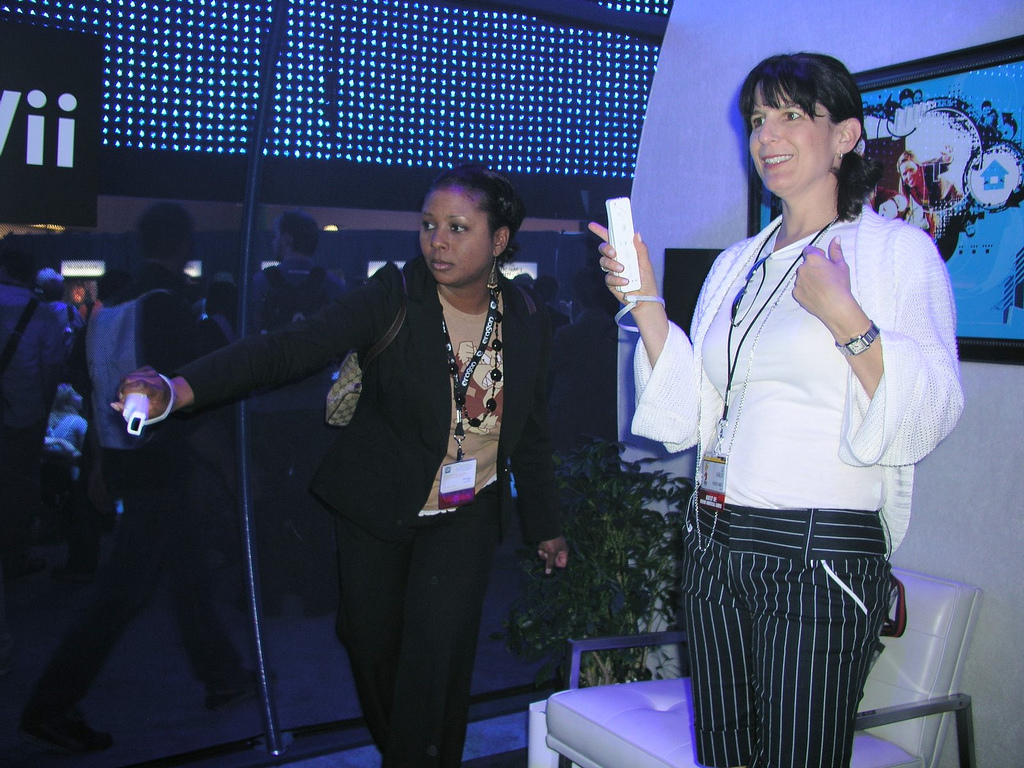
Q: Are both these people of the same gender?
A: Yes, all the people are female.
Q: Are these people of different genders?
A: No, all the people are female.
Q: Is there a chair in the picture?
A: Yes, there is a chair.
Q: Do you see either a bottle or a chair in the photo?
A: Yes, there is a chair.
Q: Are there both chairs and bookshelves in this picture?
A: No, there is a chair but no bookshelves.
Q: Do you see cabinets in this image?
A: No, there are no cabinets.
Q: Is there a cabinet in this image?
A: No, there are no cabinets.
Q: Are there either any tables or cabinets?
A: No, there are no cabinets or tables.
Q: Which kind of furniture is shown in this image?
A: The furniture is a chair.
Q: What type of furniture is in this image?
A: The furniture is a chair.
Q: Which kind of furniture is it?
A: The piece of furniture is a chair.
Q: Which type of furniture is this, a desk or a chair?
A: That is a chair.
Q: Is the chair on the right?
A: Yes, the chair is on the right of the image.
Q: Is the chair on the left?
A: No, the chair is on the right of the image.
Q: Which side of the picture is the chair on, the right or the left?
A: The chair is on the right of the image.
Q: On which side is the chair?
A: The chair is on the right of the image.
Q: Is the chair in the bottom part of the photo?
A: Yes, the chair is in the bottom of the image.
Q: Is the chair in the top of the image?
A: No, the chair is in the bottom of the image.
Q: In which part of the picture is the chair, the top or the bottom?
A: The chair is in the bottom of the image.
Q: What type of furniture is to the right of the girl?
A: The piece of furniture is a chair.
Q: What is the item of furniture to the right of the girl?
A: The piece of furniture is a chair.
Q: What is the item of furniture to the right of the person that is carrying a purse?
A: The piece of furniture is a chair.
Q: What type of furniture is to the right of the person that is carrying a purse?
A: The piece of furniture is a chair.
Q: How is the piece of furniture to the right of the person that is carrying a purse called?
A: The piece of furniture is a chair.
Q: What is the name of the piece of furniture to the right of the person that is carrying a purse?
A: The piece of furniture is a chair.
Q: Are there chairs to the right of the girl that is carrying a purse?
A: Yes, there is a chair to the right of the girl.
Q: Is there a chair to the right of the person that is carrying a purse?
A: Yes, there is a chair to the right of the girl.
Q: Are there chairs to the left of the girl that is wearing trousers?
A: No, the chair is to the right of the girl.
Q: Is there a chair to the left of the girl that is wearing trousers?
A: No, the chair is to the right of the girl.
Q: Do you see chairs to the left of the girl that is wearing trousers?
A: No, the chair is to the right of the girl.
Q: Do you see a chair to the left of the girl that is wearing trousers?
A: No, the chair is to the right of the girl.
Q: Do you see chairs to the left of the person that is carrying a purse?
A: No, the chair is to the right of the girl.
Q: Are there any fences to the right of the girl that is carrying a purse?
A: No, there is a chair to the right of the girl.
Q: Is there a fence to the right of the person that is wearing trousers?
A: No, there is a chair to the right of the girl.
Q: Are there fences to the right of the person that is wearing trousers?
A: No, there is a chair to the right of the girl.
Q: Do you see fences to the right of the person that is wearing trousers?
A: No, there is a chair to the right of the girl.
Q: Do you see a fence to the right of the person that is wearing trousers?
A: No, there is a chair to the right of the girl.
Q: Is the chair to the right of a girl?
A: Yes, the chair is to the right of a girl.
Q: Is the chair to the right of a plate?
A: No, the chair is to the right of a girl.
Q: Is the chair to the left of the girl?
A: No, the chair is to the right of the girl.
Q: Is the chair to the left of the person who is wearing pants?
A: No, the chair is to the right of the girl.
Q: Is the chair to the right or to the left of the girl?
A: The chair is to the right of the girl.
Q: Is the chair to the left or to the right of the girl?
A: The chair is to the right of the girl.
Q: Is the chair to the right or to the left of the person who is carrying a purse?
A: The chair is to the right of the girl.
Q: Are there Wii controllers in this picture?
A: Yes, there is a Wii controller.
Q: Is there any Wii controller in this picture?
A: Yes, there is a Wii controller.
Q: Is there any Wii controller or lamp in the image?
A: Yes, there is a Wii controller.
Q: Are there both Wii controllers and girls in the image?
A: Yes, there are both a Wii controller and a girl.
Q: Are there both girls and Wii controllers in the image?
A: Yes, there are both a Wii controller and a girl.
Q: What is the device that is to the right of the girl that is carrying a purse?
A: The device is a Wii controller.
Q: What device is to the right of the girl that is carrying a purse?
A: The device is a Wii controller.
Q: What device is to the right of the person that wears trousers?
A: The device is a Wii controller.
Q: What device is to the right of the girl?
A: The device is a Wii controller.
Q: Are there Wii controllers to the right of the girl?
A: Yes, there is a Wii controller to the right of the girl.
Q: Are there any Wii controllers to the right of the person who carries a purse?
A: Yes, there is a Wii controller to the right of the girl.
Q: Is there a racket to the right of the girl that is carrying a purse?
A: No, there is a Wii controller to the right of the girl.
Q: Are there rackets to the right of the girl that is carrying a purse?
A: No, there is a Wii controller to the right of the girl.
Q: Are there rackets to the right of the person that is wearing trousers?
A: No, there is a Wii controller to the right of the girl.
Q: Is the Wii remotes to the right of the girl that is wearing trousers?
A: Yes, the Wii remotes is to the right of the girl.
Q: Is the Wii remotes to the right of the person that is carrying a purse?
A: Yes, the Wii remotes is to the right of the girl.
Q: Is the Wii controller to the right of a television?
A: No, the Wii controller is to the right of the girl.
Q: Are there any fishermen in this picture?
A: No, there are no fishermen.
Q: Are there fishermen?
A: No, there are no fishermen.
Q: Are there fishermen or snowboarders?
A: No, there are no fishermen or snowboarders.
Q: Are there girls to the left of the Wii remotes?
A: Yes, there is a girl to the left of the Wii remotes.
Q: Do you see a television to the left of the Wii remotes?
A: No, there is a girl to the left of the Wii remotes.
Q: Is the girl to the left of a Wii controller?
A: Yes, the girl is to the left of a Wii controller.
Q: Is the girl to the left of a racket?
A: No, the girl is to the left of a Wii controller.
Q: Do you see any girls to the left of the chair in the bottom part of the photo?
A: Yes, there is a girl to the left of the chair.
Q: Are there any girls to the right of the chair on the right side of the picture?
A: No, the girl is to the left of the chair.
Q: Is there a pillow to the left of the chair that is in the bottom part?
A: No, there is a girl to the left of the chair.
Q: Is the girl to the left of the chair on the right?
A: Yes, the girl is to the left of the chair.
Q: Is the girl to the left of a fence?
A: No, the girl is to the left of the chair.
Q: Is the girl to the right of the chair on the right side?
A: No, the girl is to the left of the chair.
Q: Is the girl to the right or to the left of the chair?
A: The girl is to the left of the chair.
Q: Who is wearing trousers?
A: The girl is wearing trousers.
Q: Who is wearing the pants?
A: The girl is wearing trousers.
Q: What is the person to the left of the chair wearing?
A: The girl is wearing trousers.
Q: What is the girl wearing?
A: The girl is wearing trousers.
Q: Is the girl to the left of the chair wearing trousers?
A: Yes, the girl is wearing trousers.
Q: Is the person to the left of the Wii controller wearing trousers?
A: Yes, the girl is wearing trousers.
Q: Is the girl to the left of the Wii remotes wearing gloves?
A: No, the girl is wearing trousers.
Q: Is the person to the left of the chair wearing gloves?
A: No, the girl is wearing trousers.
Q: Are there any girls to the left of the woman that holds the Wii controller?
A: Yes, there is a girl to the left of the woman.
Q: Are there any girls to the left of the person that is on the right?
A: Yes, there is a girl to the left of the woman.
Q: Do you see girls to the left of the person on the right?
A: Yes, there is a girl to the left of the woman.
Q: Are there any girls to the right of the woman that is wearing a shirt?
A: No, the girl is to the left of the woman.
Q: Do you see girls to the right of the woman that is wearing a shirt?
A: No, the girl is to the left of the woman.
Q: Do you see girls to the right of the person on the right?
A: No, the girl is to the left of the woman.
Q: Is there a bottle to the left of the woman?
A: No, there is a girl to the left of the woman.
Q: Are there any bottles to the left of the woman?
A: No, there is a girl to the left of the woman.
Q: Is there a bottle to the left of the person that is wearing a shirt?
A: No, there is a girl to the left of the woman.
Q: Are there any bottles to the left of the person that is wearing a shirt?
A: No, there is a girl to the left of the woman.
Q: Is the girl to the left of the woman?
A: Yes, the girl is to the left of the woman.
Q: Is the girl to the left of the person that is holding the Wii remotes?
A: Yes, the girl is to the left of the woman.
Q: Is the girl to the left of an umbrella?
A: No, the girl is to the left of the woman.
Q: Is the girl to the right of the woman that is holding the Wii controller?
A: No, the girl is to the left of the woman.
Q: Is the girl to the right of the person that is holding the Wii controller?
A: No, the girl is to the left of the woman.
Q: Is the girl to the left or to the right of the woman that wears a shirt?
A: The girl is to the left of the woman.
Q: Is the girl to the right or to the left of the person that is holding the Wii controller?
A: The girl is to the left of the woman.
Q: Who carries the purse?
A: The girl carries the purse.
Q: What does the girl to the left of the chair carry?
A: The girl carries a purse.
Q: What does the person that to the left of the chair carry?
A: The girl carries a purse.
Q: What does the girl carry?
A: The girl carries a purse.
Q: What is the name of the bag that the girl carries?
A: The bag is a purse.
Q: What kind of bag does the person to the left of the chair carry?
A: The girl carries a purse.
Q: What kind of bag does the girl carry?
A: The girl carries a purse.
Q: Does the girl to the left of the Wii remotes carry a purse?
A: Yes, the girl carries a purse.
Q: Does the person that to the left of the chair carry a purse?
A: Yes, the girl carries a purse.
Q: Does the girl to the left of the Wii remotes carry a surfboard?
A: No, the girl carries a purse.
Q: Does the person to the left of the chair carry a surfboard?
A: No, the girl carries a purse.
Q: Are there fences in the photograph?
A: No, there are no fences.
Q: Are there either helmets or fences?
A: No, there are no fences or helmets.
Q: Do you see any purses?
A: Yes, there is a purse.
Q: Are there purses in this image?
A: Yes, there is a purse.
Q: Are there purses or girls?
A: Yes, there is a purse.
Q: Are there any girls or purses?
A: Yes, there is a purse.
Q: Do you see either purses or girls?
A: Yes, there is a purse.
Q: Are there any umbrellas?
A: No, there are no umbrellas.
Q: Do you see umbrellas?
A: No, there are no umbrellas.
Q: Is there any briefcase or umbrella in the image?
A: No, there are no umbrellas or briefcases.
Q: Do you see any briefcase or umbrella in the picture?
A: No, there are no umbrellas or briefcases.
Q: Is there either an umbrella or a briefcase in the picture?
A: No, there are no umbrellas or briefcases.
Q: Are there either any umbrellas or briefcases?
A: No, there are no umbrellas or briefcases.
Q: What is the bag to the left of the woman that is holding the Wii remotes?
A: The bag is a purse.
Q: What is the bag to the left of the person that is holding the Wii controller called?
A: The bag is a purse.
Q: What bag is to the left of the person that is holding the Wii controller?
A: The bag is a purse.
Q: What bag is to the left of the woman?
A: The bag is a purse.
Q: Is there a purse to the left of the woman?
A: Yes, there is a purse to the left of the woman.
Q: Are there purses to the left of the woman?
A: Yes, there is a purse to the left of the woman.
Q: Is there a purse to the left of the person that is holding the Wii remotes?
A: Yes, there is a purse to the left of the woman.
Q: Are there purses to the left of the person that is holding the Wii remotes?
A: Yes, there is a purse to the left of the woman.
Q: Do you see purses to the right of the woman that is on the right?
A: No, the purse is to the left of the woman.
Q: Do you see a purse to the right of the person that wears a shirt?
A: No, the purse is to the left of the woman.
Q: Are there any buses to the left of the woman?
A: No, there is a purse to the left of the woman.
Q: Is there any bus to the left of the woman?
A: No, there is a purse to the left of the woman.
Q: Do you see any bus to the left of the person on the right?
A: No, there is a purse to the left of the woman.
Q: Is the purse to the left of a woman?
A: Yes, the purse is to the left of a woman.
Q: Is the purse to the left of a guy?
A: No, the purse is to the left of a woman.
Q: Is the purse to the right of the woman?
A: No, the purse is to the left of the woman.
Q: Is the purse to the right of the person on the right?
A: No, the purse is to the left of the woman.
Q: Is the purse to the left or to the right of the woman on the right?
A: The purse is to the left of the woman.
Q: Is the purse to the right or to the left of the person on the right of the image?
A: The purse is to the left of the woman.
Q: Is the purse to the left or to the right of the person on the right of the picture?
A: The purse is to the left of the woman.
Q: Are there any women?
A: Yes, there is a woman.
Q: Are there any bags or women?
A: Yes, there is a woman.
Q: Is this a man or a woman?
A: This is a woman.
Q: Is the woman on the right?
A: Yes, the woman is on the right of the image.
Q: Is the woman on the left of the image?
A: No, the woman is on the right of the image.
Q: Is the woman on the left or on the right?
A: The woman is on the right of the image.